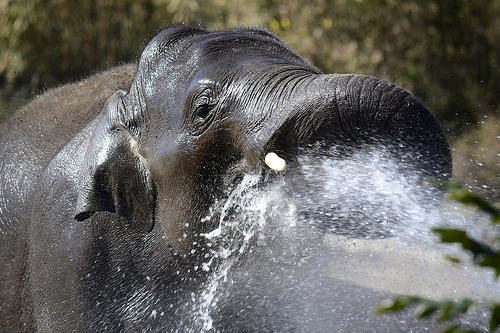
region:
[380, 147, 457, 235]
water droplets spraying an elephant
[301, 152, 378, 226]
water droplets spraying an elephant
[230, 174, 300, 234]
water droplets spraying an elephant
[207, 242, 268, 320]
water droplets spraying an elephant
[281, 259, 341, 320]
water droplets spraying an elephant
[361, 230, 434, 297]
water droplets spraying an elephant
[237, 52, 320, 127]
elephant's wrinkly grey skin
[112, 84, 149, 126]
elephant's wrinkly grey skin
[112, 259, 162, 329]
elephant's wrinkly grey skin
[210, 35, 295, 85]
elephant's wrinkly grey skin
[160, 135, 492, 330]
Water splashes caused by the elephant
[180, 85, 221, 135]
Right eye of the elephant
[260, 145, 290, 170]
White right tusk of the elephant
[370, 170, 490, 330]
Green leaves in front of the elephant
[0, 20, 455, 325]
Dark brown elephant drinking water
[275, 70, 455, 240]
Dark brown trunk of the elephant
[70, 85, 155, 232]
Right ear flap of the elephant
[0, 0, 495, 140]
Forest of trees in the background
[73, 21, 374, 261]
Head of the elephant drinking water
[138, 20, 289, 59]
Dark brown head of the elephant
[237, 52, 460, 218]
the trunk of a elephant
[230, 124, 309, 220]
the tusk of a elephant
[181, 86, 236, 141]
the eye of a elephant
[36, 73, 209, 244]
the ear of a elephant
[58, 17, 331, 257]
the head of a elephant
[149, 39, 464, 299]
a elephant drinking water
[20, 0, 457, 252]
a big grey elephant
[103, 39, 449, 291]
a elephant splashing water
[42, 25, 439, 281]
the back of a elephant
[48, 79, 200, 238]
the grey ear of a big elephant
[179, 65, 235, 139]
a right eye on an animal.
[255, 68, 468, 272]
an elephant spraying water.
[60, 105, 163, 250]
a right ear of an elephant.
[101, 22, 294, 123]
the top of an elephant's head.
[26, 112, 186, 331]
a right front elephant arm.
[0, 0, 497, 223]
a forest filled with trees.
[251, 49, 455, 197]
a trunk on an elephant.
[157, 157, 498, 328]
water spraying out of a trunk.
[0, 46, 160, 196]
The back of an elephant.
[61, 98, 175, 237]
A right front elephant ear.